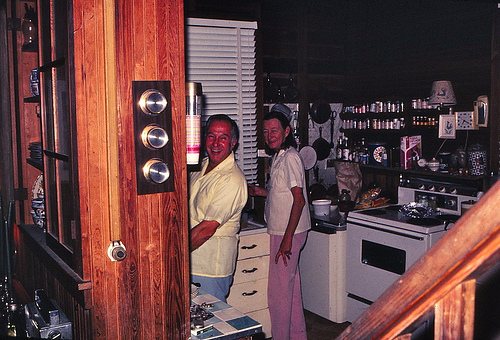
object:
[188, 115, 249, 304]
man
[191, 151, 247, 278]
shirt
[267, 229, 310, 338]
pants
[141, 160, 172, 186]
dial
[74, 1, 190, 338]
wall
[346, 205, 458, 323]
stove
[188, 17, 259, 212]
blinds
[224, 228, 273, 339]
cabinets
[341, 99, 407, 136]
seasonings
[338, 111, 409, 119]
shelf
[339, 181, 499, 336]
bannister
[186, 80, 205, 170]
dispenser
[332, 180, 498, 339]
rail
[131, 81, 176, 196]
barometer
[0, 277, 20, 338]
trophies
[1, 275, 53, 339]
floor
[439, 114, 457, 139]
picture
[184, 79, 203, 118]
holder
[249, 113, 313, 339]
woman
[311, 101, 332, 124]
pans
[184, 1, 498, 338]
kitchen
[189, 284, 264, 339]
tiles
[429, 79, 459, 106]
lampshade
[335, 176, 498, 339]
railing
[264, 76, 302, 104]
pots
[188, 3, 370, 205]
wall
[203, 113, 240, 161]
head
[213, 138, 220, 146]
nose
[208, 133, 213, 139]
eye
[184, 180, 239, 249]
arm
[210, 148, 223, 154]
mouth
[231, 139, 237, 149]
ear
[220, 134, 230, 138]
eyebrow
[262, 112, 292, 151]
head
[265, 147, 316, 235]
shirt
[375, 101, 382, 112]
spice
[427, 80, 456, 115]
lamp